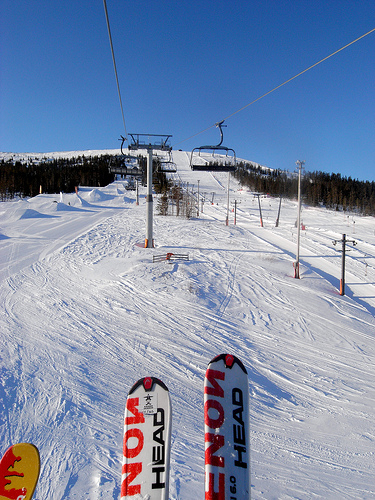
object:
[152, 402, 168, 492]
edge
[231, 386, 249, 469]
edge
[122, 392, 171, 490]
writing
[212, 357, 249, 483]
writing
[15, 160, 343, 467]
slope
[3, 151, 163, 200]
stand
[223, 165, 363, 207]
trees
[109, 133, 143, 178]
ski lift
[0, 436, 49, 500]
edge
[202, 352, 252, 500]
board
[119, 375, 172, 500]
ski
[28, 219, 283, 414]
tracks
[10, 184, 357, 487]
snow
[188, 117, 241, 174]
ski lift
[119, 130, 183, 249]
support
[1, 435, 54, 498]
ski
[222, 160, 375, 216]
forest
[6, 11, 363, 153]
sky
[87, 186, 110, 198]
hill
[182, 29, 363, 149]
wire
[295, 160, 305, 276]
pole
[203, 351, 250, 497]
ski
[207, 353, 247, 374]
tip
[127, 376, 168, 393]
tip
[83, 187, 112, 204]
ramp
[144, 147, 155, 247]
pole